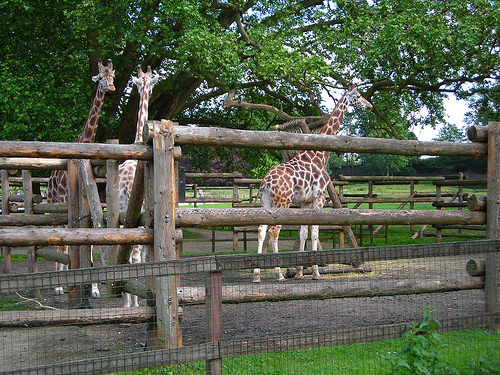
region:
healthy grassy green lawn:
[100, 325, 499, 373]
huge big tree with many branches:
[1, 0, 498, 177]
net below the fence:
[1, 242, 499, 373]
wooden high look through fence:
[1, 119, 498, 371]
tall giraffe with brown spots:
[253, 84, 370, 281]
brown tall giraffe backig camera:
[118, 62, 159, 306]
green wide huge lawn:
[150, 175, 487, 245]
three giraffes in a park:
[46, 57, 371, 312]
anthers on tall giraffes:
[97, 59, 117, 71]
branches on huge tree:
[87, 4, 478, 198]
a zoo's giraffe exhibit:
[0, 0, 499, 374]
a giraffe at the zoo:
[251, 82, 373, 283]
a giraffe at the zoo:
[117, 64, 158, 306]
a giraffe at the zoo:
[47, 58, 115, 298]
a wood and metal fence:
[0, 238, 499, 374]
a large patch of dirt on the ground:
[0, 252, 486, 371]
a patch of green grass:
[100, 327, 498, 374]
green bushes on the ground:
[375, 304, 499, 374]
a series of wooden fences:
[0, 118, 499, 350]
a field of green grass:
[0, 180, 487, 247]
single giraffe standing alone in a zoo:
[210, 84, 391, 289]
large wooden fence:
[138, 116, 485, 349]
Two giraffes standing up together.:
[36, 28, 180, 351]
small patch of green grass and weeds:
[86, 310, 498, 367]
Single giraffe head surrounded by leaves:
[69, 46, 124, 135]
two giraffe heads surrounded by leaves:
[60, 46, 188, 146]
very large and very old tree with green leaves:
[14, 21, 496, 160]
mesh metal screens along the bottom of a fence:
[2, 232, 494, 372]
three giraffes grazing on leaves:
[40, 43, 410, 294]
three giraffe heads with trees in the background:
[55, 48, 387, 123]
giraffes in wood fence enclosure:
[47, 49, 385, 324]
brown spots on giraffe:
[283, 167, 320, 184]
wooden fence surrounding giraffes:
[3, 108, 496, 365]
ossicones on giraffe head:
[131, 60, 158, 75]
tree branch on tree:
[191, 70, 315, 118]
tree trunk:
[95, 91, 168, 158]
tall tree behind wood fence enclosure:
[4, 0, 482, 213]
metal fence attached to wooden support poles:
[5, 234, 497, 374]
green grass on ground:
[166, 323, 498, 373]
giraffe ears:
[88, 69, 103, 85]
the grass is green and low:
[310, 355, 340, 371]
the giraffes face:
[85, 70, 122, 95]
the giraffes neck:
[131, 98, 152, 120]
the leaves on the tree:
[260, 43, 310, 86]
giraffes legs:
[248, 228, 278, 248]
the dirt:
[290, 307, 323, 322]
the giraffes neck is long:
[90, 101, 100, 117]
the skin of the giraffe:
[272, 161, 302, 181]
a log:
[85, 227, 145, 242]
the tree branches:
[383, 69, 428, 100]